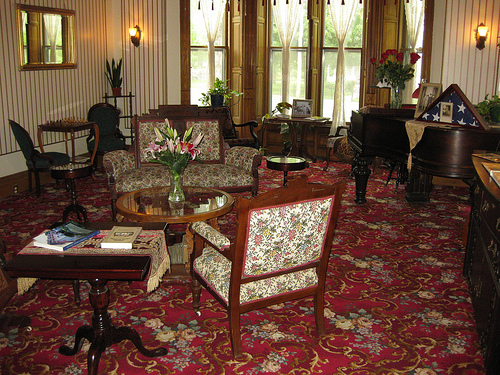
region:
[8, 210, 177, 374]
Table in the forefront.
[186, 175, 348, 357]
chair beside the table.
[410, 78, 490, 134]
Flag on the piano.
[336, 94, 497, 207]
Piano in the background.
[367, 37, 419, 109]
Vase of roses on piano.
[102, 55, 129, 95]
Plant on the shelf.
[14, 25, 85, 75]
Mirror on the wall.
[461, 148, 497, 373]
Sidebar against the wall.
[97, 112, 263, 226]
Flowered pattern on the couch.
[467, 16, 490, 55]
Light on the wall.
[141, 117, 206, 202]
Clear vase with assortment of flowers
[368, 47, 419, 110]
Clear vase with several red roses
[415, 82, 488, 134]
Veteran burial flag in flag case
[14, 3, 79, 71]
Mirror in a gold frame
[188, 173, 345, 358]
Wood chair with a floral print fabric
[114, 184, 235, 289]
Round wood table with glass top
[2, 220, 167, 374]
Dark wood square table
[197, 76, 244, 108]
Greenery in a flower pot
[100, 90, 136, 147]
Wood 3-tier corner shelf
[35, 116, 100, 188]
Wood table with chess set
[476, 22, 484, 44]
LIGHTS ON THE WALL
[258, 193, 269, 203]
CHAIR TRIMMED IN WOOD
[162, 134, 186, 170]
FLOWERS IN A VASE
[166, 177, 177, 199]
GLASS VASE ON THE TABLE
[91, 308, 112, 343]
BOTTOM OF TABLE MADE OUT OF WOOD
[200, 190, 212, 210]
TOP OF TABLE IS GLASS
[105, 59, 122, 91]
FLOWER ON THE SHELF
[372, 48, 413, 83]
ROSES IN A VASE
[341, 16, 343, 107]
SHEER CURTAINS AT THE WINDOW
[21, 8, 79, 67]
MIRROR ON THE WALL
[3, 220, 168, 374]
An antique wooden end table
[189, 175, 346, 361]
A wooden upholstered chair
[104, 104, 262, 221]
A wooden upholstered love seat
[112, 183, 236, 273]
A wood and glass coffee table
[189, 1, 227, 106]
A tall window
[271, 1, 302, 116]
A white curtain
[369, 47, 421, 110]
A bouquet of red roses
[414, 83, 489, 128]
A folded and framed American flag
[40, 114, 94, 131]
A table top chess board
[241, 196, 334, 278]
Floral upholstery fabric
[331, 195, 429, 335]
the floor is red in color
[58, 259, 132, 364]
the table is wooden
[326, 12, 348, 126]
window curtains are white in color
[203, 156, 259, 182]
the seats are white in color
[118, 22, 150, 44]
the light is on the wall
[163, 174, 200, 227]
flower vessel is colorles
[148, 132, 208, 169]
flower petals are white and red in color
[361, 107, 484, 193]
piano is besoide the tables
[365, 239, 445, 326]
red carpet has white flowers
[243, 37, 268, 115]
wall is brown in color